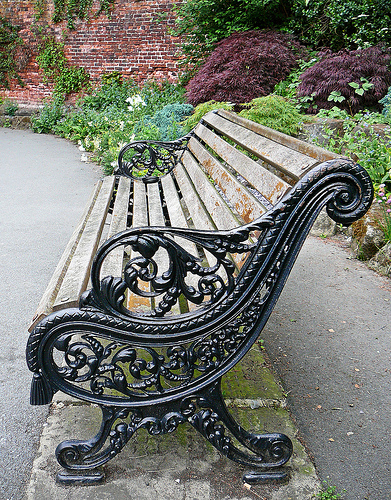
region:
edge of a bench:
[278, 394, 302, 434]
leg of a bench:
[251, 447, 263, 454]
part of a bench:
[138, 404, 165, 408]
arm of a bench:
[162, 325, 185, 338]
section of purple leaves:
[332, 76, 347, 77]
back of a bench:
[235, 151, 252, 158]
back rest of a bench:
[253, 146, 269, 149]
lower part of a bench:
[128, 200, 164, 220]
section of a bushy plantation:
[134, 95, 171, 110]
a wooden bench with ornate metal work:
[52, 104, 356, 483]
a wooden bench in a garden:
[10, 45, 376, 490]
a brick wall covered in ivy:
[0, 2, 186, 114]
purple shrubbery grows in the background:
[183, 24, 301, 104]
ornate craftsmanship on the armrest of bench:
[51, 164, 356, 480]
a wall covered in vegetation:
[0, 2, 201, 103]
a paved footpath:
[2, 127, 84, 453]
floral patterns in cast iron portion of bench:
[57, 218, 291, 480]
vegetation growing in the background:
[178, 2, 389, 118]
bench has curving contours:
[47, 102, 355, 483]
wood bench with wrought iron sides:
[23, 104, 375, 495]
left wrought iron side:
[24, 157, 374, 405]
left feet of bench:
[55, 406, 290, 494]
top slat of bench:
[215, 105, 341, 159]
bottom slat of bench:
[25, 175, 103, 330]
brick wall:
[0, 0, 199, 102]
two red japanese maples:
[185, 29, 388, 113]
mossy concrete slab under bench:
[25, 332, 316, 494]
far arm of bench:
[114, 131, 187, 180]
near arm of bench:
[87, 220, 259, 317]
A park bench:
[65, 117, 345, 479]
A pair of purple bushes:
[179, 26, 381, 106]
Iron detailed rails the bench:
[33, 230, 296, 483]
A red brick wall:
[0, 10, 202, 124]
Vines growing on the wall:
[0, 0, 129, 107]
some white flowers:
[85, 90, 142, 168]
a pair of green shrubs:
[161, 84, 298, 161]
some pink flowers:
[363, 178, 389, 231]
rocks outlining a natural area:
[225, 114, 389, 279]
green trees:
[205, 2, 389, 53]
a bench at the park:
[16, 102, 374, 484]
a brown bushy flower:
[184, 21, 305, 101]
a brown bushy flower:
[299, 40, 390, 115]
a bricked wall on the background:
[0, 0, 196, 124]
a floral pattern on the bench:
[49, 240, 289, 395]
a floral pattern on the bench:
[105, 406, 241, 454]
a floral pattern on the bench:
[100, 235, 286, 310]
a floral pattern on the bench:
[101, 122, 195, 176]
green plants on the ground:
[31, 43, 186, 177]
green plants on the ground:
[314, 116, 389, 182]